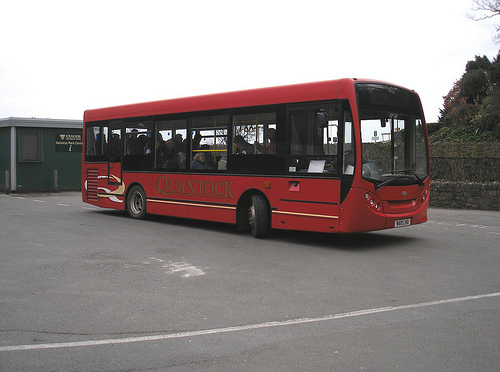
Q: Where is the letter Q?
A: On the bus.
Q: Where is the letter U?
A: On the bus.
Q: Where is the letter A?
A: On the bus.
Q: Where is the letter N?
A: On the bus.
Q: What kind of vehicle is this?
A: Bus.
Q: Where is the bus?
A: Asphalt parking lot.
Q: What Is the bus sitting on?
A: Grey asphalt.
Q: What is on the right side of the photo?
A: Trees.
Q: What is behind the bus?
A: Green building.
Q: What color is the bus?
A: Red.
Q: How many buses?
A: 1.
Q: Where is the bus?
A: Next to the wall.